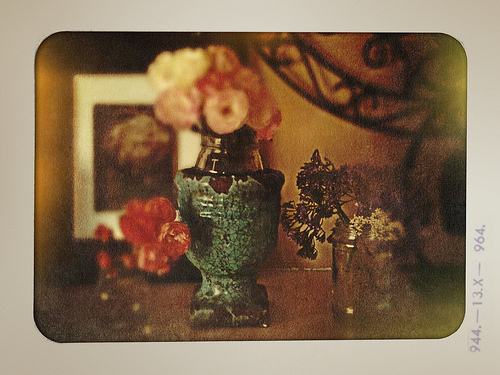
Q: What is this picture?
A: A slide photograph.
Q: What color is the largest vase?
A: Green and brown.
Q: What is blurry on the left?
A: A photograph frame.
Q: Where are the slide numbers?
A: On the right side.